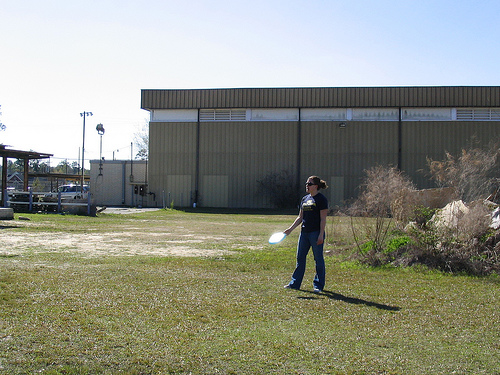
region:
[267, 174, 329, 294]
a woman holding a frisbee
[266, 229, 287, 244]
a frisbee shining in sunlight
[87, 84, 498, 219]
a building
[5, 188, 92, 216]
a fence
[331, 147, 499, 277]
some bushes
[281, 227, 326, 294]
the legs of a woman wearing blue jeans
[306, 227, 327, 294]
one leg of a woman wearing blue jeans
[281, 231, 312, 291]
one leg of a woman wearing blue jeans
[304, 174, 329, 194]
head of a woman with black sunglasses and a ponytail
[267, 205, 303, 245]
the arm of a person holding a frisbee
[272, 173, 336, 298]
Woman wearing a black shirt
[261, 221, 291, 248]
Frisbee in the woman's hand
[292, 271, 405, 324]
Shadow on the ground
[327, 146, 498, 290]
Bushes next to woman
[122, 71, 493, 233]
Building in the background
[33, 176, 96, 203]
Van in the background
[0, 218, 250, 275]
Brown spot on field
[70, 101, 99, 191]
Light pole in the background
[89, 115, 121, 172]
Light pole in the background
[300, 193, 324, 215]
Yellow logo on woman's shirt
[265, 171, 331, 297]
PERSON READY TO PLAY FRISBEE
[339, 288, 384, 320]
PART OF SHADOW OF PLAYER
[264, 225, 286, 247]
WHITE FRISBEE IN HAND OF PLAYER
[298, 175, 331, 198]
HEAD OF FRISBEE PLAYER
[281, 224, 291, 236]
HAND OF FRISBEE PLAYER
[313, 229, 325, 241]
HAND OF FRISBEE PLAYER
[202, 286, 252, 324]
GREEN GRASSY AREA NEAR PLAYER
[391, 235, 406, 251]
SMALL GREEN BUSHES NEAR PLAYER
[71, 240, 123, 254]
DIRT AREA NEAR PLAYER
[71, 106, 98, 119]
HIGH LIGHTS NEAR PLAYER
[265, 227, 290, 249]
girl is holding a frisbee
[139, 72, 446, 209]
tall building behind the girl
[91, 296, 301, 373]
green grass in the field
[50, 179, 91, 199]
vehicle parked in front of the building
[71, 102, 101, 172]
light post by the car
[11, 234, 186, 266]
dirt patch in the grass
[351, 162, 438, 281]
weeds growing in the field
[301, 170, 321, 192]
girl is wearing sunglasses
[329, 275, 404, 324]
shadow on the ground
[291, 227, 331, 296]
girl is wearing jeans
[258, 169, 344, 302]
woman holding a frisbee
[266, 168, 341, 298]
woman wearing a black t-shirt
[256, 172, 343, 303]
woman wearing blue jeans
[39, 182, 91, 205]
parked white minivan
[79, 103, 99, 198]
tall outside parking light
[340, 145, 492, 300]
group of bushes without leaves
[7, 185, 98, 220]
small metal fence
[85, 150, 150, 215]
small tan trailer building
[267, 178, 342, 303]
woman wearing sunglasses